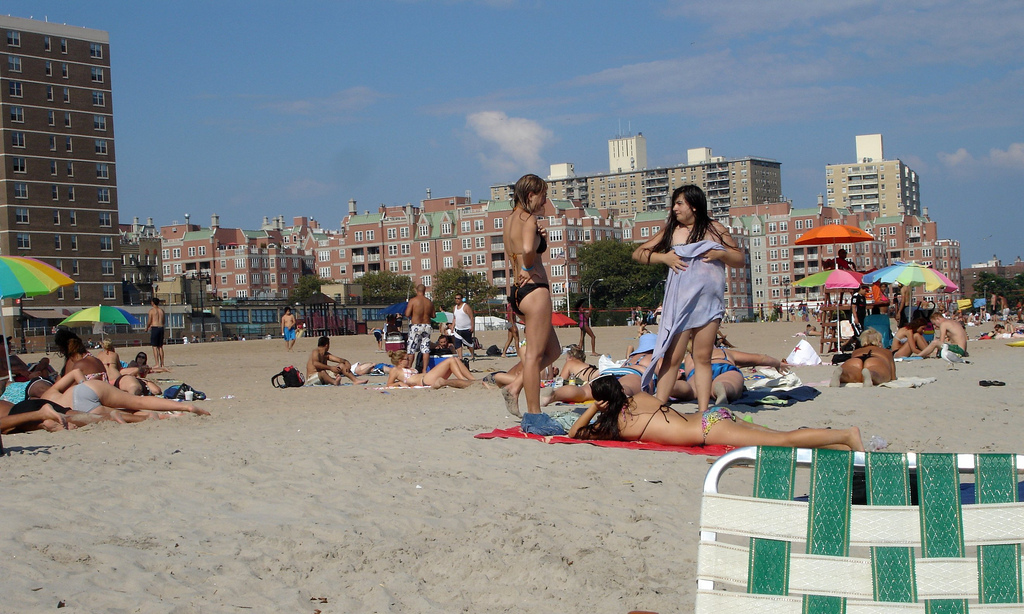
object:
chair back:
[676, 438, 1024, 611]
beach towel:
[472, 405, 807, 468]